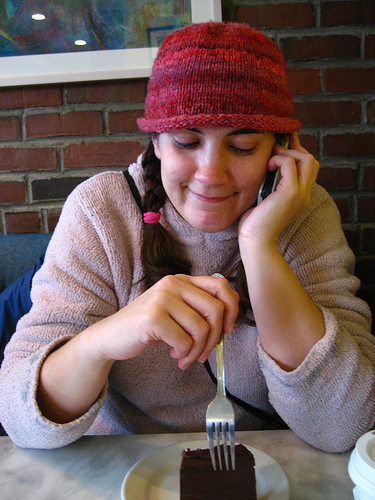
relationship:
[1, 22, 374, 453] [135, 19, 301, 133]
woman wearing hat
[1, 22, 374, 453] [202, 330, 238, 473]
woman holding fork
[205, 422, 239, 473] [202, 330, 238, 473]
tines on fork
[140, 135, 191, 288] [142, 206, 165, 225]
braid held by elastic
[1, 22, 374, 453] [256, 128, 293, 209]
woman holding cellphone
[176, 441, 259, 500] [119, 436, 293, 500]
cake on top of plate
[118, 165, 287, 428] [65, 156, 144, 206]
strap across shoulder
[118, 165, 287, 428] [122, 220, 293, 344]
strap across chest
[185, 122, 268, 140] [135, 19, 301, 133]
eyebrows below hat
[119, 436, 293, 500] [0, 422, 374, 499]
plate on top of table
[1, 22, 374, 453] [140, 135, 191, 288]
woman with braid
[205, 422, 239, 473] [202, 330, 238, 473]
tines on end of fork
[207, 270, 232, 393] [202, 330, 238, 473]
handle of fork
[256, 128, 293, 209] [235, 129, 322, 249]
cellphone held by hand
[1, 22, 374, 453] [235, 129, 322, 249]
woman has hand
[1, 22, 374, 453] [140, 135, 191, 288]
woman has braid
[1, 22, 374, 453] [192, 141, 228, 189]
woman has nose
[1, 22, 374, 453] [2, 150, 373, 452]
woman wearing sweater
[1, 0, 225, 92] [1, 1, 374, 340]
picture hung on wall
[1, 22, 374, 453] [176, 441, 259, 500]
woman eating cake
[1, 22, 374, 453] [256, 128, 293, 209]
woman talking on cellphone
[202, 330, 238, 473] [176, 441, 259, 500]
fork entering cake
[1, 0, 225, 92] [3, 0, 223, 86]
picture inside frame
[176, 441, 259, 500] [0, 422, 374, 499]
cake on top of table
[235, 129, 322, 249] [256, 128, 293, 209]
hand holding onto cellphone